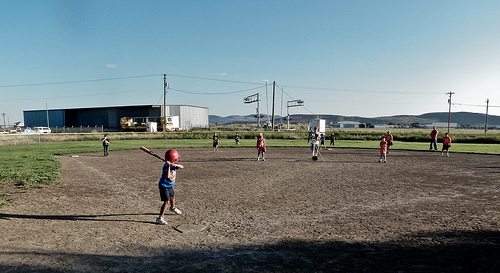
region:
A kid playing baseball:
[153, 136, 198, 255]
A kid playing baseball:
[173, 148, 222, 258]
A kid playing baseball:
[106, 100, 209, 270]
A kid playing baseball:
[148, 133, 230, 241]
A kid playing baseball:
[141, 144, 196, 193]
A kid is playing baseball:
[127, 138, 284, 270]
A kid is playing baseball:
[142, 102, 234, 221]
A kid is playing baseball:
[136, 147, 215, 231]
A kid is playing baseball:
[93, 56, 212, 271]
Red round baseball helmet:
[165, 147, 181, 163]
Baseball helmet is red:
[165, 146, 180, 161]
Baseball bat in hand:
[137, 142, 167, 167]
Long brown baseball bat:
[140, 142, 173, 168]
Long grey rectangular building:
[21, 100, 209, 128]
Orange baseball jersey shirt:
[378, 138, 388, 153]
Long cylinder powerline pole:
[160, 71, 166, 129]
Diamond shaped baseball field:
[2, 142, 497, 270]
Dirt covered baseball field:
[0, 143, 497, 269]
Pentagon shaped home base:
[173, 219, 208, 235]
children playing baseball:
[141, 141, 184, 229]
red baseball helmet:
[162, 144, 184, 161]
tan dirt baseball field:
[76, 155, 414, 245]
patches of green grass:
[0, 171, 71, 211]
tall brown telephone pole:
[436, 86, 461, 128]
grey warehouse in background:
[25, 103, 218, 133]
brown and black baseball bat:
[138, 131, 178, 168]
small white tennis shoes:
[155, 207, 185, 227]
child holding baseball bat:
[140, 137, 190, 225]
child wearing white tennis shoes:
[146, 139, 183, 228]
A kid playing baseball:
[160, 197, 214, 268]